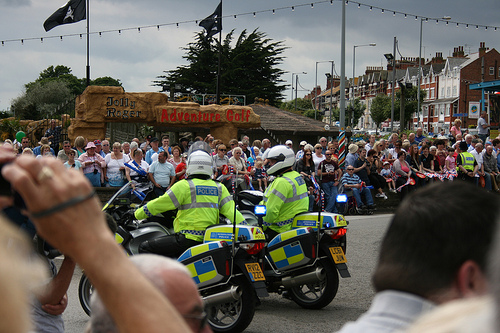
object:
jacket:
[257, 169, 309, 234]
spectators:
[1, 108, 499, 215]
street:
[49, 210, 389, 333]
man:
[455, 141, 479, 189]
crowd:
[0, 112, 499, 214]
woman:
[295, 148, 316, 190]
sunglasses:
[305, 154, 311, 157]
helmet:
[185, 150, 214, 178]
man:
[126, 149, 249, 262]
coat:
[133, 177, 250, 243]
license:
[245, 262, 267, 282]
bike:
[77, 180, 270, 332]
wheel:
[204, 270, 258, 333]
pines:
[148, 26, 294, 109]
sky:
[1, 0, 498, 110]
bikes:
[214, 174, 351, 311]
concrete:
[51, 210, 394, 333]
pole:
[338, 0, 346, 195]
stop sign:
[240, 242, 268, 254]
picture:
[0, 0, 499, 333]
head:
[267, 144, 297, 176]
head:
[185, 150, 214, 179]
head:
[130, 148, 144, 161]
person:
[125, 147, 150, 191]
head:
[112, 142, 121, 155]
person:
[103, 142, 130, 187]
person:
[77, 141, 106, 187]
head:
[86, 142, 96, 155]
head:
[100, 140, 110, 151]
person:
[101, 140, 111, 159]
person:
[339, 165, 377, 210]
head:
[345, 165, 354, 175]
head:
[324, 150, 332, 160]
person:
[317, 150, 343, 214]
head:
[383, 161, 391, 169]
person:
[379, 161, 397, 193]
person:
[0, 143, 193, 333]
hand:
[0, 153, 105, 255]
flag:
[197, 0, 223, 39]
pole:
[215, 30, 222, 104]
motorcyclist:
[233, 144, 310, 308]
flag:
[42, 0, 88, 33]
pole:
[85, 0, 91, 82]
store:
[66, 84, 352, 145]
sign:
[160, 108, 251, 122]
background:
[0, 0, 480, 149]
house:
[411, 43, 500, 137]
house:
[383, 51, 448, 136]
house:
[347, 66, 388, 131]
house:
[311, 72, 351, 127]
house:
[302, 85, 321, 111]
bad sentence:
[367, 246, 373, 250]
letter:
[161, 109, 169, 123]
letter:
[169, 108, 177, 122]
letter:
[203, 112, 210, 121]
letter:
[226, 109, 234, 122]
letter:
[245, 109, 251, 122]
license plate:
[328, 246, 347, 263]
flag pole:
[85, 0, 90, 86]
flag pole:
[216, 0, 223, 104]